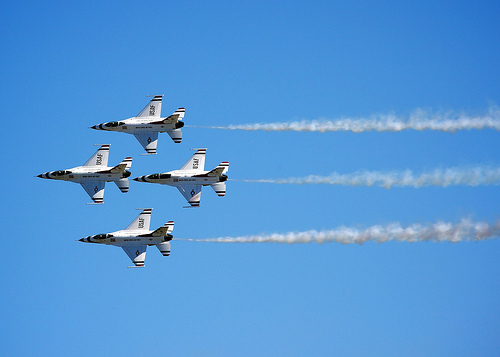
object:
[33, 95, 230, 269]
jets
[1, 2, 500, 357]
sky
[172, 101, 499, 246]
trails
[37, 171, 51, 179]
nose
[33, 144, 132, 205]
jet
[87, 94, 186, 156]
jet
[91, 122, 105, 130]
nose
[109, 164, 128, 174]
rudder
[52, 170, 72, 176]
cockpit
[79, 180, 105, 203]
wing